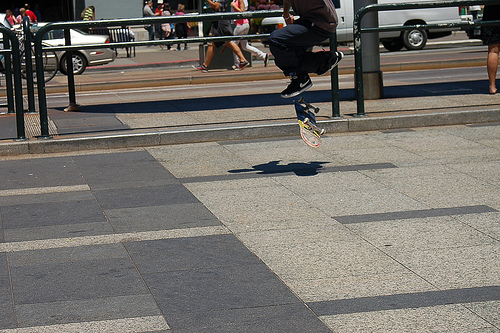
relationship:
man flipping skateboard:
[244, 15, 349, 168] [282, 97, 331, 151]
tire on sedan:
[55, 47, 89, 79] [3, 19, 120, 79]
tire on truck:
[396, 21, 432, 55] [261, 5, 468, 47]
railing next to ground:
[30, 9, 498, 136] [2, 95, 496, 329]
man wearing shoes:
[268, 1, 344, 98] [268, 65, 328, 108]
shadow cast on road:
[226, 159, 333, 176] [2, 120, 497, 330]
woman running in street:
[173, 2, 188, 49] [8, 24, 496, 90]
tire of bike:
[9, 38, 62, 84] [1, 23, 58, 83]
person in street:
[226, 1, 268, 68] [59, 37, 498, 75]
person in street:
[196, 1, 249, 66] [59, 37, 498, 75]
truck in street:
[259, 0, 481, 52] [0, 31, 496, 64]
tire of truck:
[400, 28, 428, 50] [261, 3, 475, 61]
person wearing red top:
[7, 2, 37, 24] [24, 2, 36, 23]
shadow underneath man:
[226, 159, 333, 176] [268, 1, 344, 98]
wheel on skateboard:
[298, 113, 313, 127] [290, 96, 332, 153]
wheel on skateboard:
[319, 124, 329, 138] [290, 96, 332, 153]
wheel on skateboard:
[293, 93, 305, 105] [290, 96, 332, 153]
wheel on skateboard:
[312, 104, 322, 115] [290, 96, 332, 153]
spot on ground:
[382, 240, 392, 249] [6, 19, 496, 331]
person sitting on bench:
[118, 22, 135, 58] [91, 20, 138, 57]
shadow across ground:
[232, 153, 327, 190] [9, 131, 499, 330]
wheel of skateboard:
[303, 117, 309, 125] [300, 114, 309, 126]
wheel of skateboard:
[303, 117, 309, 125] [291, 92, 330, 152]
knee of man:
[252, 23, 307, 64] [261, 2, 350, 100]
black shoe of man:
[280, 72, 313, 98] [272, 3, 349, 115]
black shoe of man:
[281, 72, 313, 99] [263, 0, 345, 97]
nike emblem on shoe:
[298, 79, 312, 87] [279, 72, 314, 99]